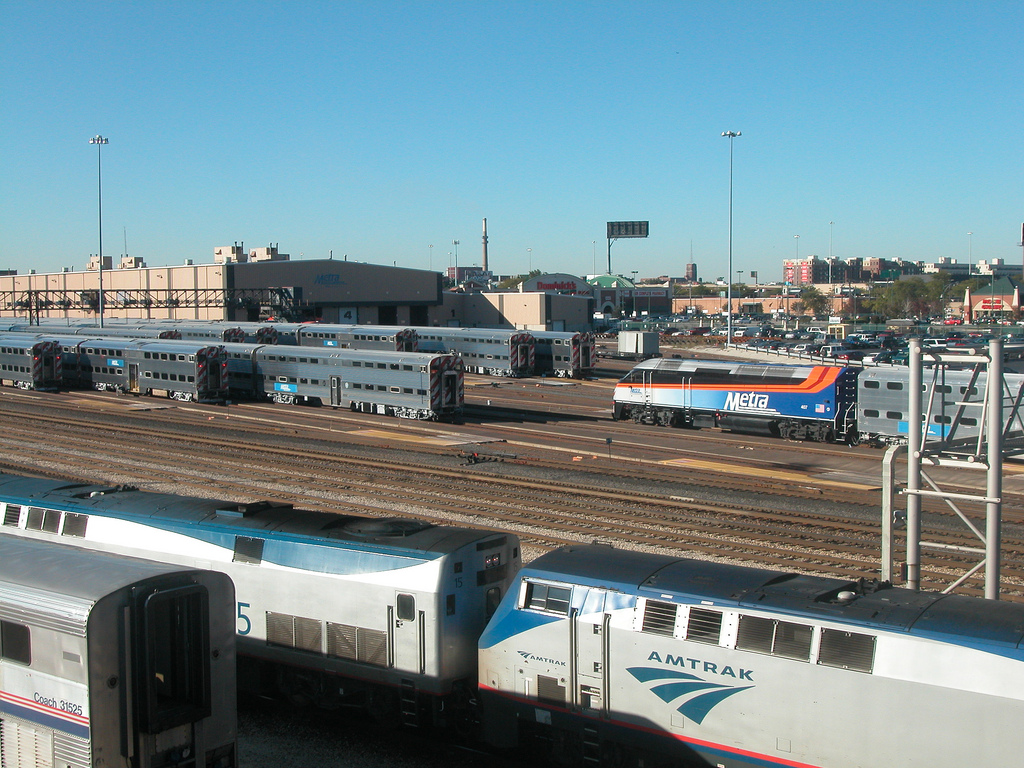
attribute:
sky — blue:
[6, 5, 1022, 290]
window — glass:
[257, 618, 488, 755]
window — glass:
[527, 583, 576, 615]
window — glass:
[634, 368, 654, 384]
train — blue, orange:
[231, 339, 475, 423]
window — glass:
[627, 368, 644, 387]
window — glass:
[864, 377, 880, 391]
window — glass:
[367, 381, 391, 394]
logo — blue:
[612, 643, 768, 741]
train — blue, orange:
[586, 328, 1020, 477]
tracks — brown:
[0, 383, 888, 584]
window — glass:
[622, 363, 808, 389]